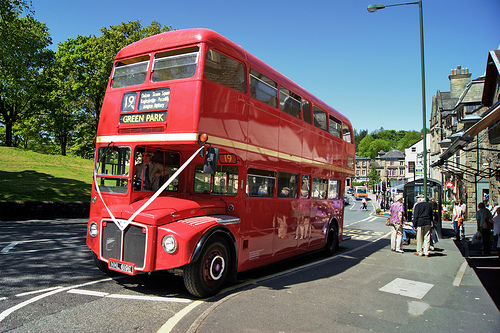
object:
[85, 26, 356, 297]
bus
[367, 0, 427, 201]
light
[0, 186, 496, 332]
road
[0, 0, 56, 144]
tree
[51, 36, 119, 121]
tree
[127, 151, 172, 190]
driver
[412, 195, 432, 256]
man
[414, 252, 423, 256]
shoe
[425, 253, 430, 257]
shoe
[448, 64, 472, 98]
chimney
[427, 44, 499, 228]
building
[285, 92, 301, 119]
man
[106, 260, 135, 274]
license plate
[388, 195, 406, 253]
person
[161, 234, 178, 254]
headlight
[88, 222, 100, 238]
headlight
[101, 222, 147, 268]
grill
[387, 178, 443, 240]
bus stop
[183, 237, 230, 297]
wheel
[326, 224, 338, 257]
wheel